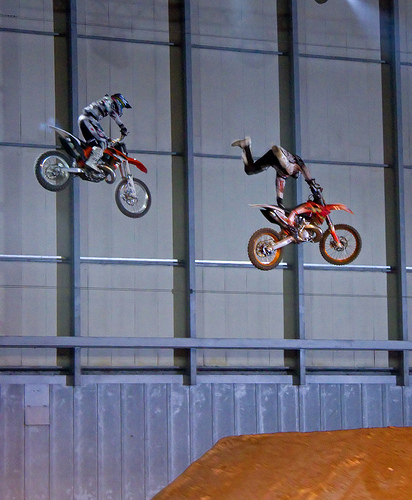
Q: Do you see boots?
A: Yes, there are boots.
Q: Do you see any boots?
A: Yes, there are boots.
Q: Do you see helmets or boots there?
A: Yes, there are boots.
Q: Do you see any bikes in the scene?
A: Yes, there is a bike.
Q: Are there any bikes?
A: Yes, there is a bike.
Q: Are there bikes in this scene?
A: Yes, there is a bike.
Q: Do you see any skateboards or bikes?
A: Yes, there is a bike.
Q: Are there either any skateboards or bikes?
A: Yes, there is a bike.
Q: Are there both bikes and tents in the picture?
A: No, there is a bike but no tents.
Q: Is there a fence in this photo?
A: No, there are no fences.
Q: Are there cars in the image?
A: No, there are no cars.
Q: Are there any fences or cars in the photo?
A: No, there are no cars or fences.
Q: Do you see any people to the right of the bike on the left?
A: Yes, there are people to the right of the bike.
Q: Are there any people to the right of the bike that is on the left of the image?
A: Yes, there are people to the right of the bike.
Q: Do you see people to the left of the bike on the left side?
A: No, the people are to the right of the bike.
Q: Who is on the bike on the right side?
A: The people are on the bike.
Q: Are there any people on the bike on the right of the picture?
A: Yes, there are people on the bike.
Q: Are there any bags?
A: No, there are no bags.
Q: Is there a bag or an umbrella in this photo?
A: No, there are no bags or umbrellas.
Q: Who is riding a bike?
A: The people are riding a bike.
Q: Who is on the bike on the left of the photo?
A: The people are on the bike.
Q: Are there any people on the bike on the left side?
A: Yes, there are people on the bike.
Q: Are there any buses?
A: No, there are no buses.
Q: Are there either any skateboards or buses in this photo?
A: No, there are no buses or skateboards.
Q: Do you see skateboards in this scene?
A: No, there are no skateboards.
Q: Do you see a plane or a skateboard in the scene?
A: No, there are no skateboards or airplanes.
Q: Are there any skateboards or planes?
A: No, there are no skateboards or planes.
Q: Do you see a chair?
A: No, there are no chairs.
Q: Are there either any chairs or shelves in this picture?
A: No, there are no chairs or shelves.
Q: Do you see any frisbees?
A: No, there are no frisbees.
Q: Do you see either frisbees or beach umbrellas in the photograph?
A: No, there are no frisbees or beach umbrellas.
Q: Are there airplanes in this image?
A: No, there are no airplanes.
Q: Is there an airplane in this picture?
A: No, there are no airplanes.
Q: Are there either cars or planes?
A: No, there are no planes or cars.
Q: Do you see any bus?
A: No, there are no buses.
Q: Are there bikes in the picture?
A: Yes, there is a bike.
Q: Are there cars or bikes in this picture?
A: Yes, there is a bike.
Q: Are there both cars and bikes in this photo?
A: No, there is a bike but no cars.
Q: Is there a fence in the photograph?
A: No, there are no fences.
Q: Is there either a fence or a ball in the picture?
A: No, there are no fences or balls.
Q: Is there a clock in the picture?
A: No, there are no clocks.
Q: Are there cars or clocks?
A: No, there are no clocks or cars.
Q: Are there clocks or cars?
A: No, there are no clocks or cars.